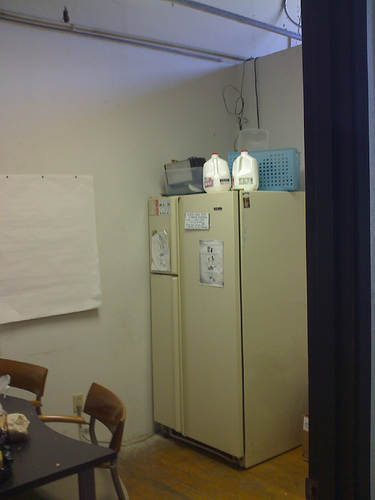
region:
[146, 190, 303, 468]
a tall refrigerator with a freezer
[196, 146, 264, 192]
milk jugs on top of the refrigerator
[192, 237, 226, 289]
a paper on the refrigerator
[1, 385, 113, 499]
a table in front of the refrigerator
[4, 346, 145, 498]
chairs at the table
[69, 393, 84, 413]
an outlet on the wall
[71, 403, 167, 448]
the refrigerator cord plugged into the wall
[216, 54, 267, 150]
cords hanging over the wall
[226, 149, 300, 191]
a blue container on top of the refrigerator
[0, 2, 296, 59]
metal pipes on the wall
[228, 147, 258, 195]
milk on a refrigerator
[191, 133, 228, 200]
milk on a refrigerator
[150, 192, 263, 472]
tall beige refigerator next to wall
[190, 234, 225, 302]
paper on refrigerator door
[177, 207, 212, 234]
paper on refrigerator door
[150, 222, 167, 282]
paper on a refrigerator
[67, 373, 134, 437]
chair next to table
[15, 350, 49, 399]
chair next to table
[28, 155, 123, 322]
paper on a wall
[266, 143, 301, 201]
basket on a refrigerator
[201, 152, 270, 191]
milk jugs on top of fridge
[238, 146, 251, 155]
red cap on top of jug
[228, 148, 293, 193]
blue basket on top of fridge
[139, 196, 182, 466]
freezer next to fridge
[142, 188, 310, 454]
large freezer and fridge combo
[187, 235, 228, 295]
piece of paper on fridge front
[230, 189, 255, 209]
magnet on side of fridge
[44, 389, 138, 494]
brown chair in kitchen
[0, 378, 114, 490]
black table in kitchen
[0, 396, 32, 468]
food on top of kitchen table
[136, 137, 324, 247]
Two milk containers on top of the refrigerator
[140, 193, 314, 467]
Beige double door refrigerator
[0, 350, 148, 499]
Dining table and chairs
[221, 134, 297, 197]
Blue basket on the fridge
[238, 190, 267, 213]
Fridge magnet on the side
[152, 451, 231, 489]
Wooden floor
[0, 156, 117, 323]
White board on the wall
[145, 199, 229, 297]
Papers on the fridge door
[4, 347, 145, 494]
Two brown dining chair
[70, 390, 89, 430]
Electric socket and plug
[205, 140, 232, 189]
The gallon of milk on the left side.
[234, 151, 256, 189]
The gallon of milk on the right side.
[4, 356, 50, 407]
The wooden chair on the left.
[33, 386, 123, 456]
The wooden chair on the right.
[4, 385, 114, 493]
The black table in front of the chairs.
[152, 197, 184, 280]
The top left door of the fridge.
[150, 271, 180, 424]
The bottom left door on the fridge.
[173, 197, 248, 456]
The long right door of the fridge.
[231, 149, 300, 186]
The blue basket behind the gallons of milk.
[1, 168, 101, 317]
The white paper thumbtacked to the wall.